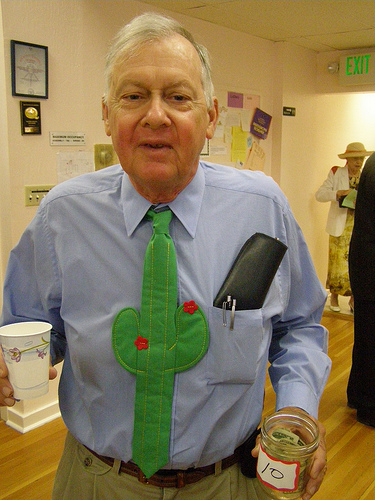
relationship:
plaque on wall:
[13, 39, 50, 96] [2, 2, 374, 368]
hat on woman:
[330, 138, 369, 158] [307, 140, 373, 317]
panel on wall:
[21, 186, 59, 211] [3, 2, 371, 477]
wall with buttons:
[3, 2, 371, 477] [26, 195, 46, 199]